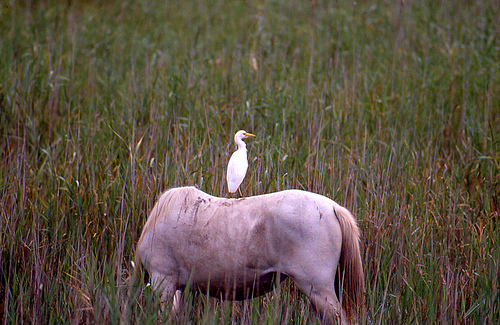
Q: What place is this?
A: It is a field.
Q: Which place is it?
A: It is a field.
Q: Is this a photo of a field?
A: Yes, it is showing a field.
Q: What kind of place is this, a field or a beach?
A: It is a field.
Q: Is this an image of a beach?
A: No, the picture is showing a field.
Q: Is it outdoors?
A: Yes, it is outdoors.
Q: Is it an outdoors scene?
A: Yes, it is outdoors.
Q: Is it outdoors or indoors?
A: It is outdoors.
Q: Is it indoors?
A: No, it is outdoors.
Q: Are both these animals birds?
A: No, they are horses and birds.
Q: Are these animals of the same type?
A: No, they are horses and birds.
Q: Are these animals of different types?
A: Yes, they are horses and birds.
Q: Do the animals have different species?
A: Yes, they are horses and birds.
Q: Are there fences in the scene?
A: No, there are no fences.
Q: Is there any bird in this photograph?
A: Yes, there is a bird.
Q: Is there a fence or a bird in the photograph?
A: Yes, there is a bird.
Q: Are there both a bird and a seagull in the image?
A: No, there is a bird but no seagulls.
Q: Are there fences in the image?
A: No, there are no fences.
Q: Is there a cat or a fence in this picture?
A: No, there are no fences or cats.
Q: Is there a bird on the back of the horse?
A: Yes, there is a bird on the back of the horse.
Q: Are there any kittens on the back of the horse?
A: No, there is a bird on the back of the horse.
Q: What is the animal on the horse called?
A: The animal is a bird.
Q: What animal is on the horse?
A: The animal is a bird.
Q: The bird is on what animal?
A: The bird is on the horse.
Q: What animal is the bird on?
A: The bird is on the horse.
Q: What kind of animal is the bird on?
A: The bird is on the horse.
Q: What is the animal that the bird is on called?
A: The animal is a horse.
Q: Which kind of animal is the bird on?
A: The bird is on the horse.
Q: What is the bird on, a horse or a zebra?
A: The bird is on a horse.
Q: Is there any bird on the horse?
A: Yes, there is a bird on the horse.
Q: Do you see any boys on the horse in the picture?
A: No, there is a bird on the horse.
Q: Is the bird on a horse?
A: Yes, the bird is on a horse.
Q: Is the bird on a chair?
A: No, the bird is on a horse.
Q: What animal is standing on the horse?
A: The bird is standing on the horse.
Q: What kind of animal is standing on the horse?
A: The animal is a bird.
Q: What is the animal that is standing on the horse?
A: The animal is a bird.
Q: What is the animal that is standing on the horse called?
A: The animal is a bird.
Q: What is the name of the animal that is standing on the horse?
A: The animal is a bird.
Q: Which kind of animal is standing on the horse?
A: The animal is a bird.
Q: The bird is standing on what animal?
A: The bird is standing on the horse.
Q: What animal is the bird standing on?
A: The bird is standing on the horse.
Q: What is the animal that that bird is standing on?
A: The animal is a horse.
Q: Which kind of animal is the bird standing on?
A: The bird is standing on the horse.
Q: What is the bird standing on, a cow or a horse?
A: The bird is standing on a horse.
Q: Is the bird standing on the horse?
A: Yes, the bird is standing on the horse.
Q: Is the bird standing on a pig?
A: No, the bird is standing on the horse.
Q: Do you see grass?
A: Yes, there is grass.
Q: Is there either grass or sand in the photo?
A: Yes, there is grass.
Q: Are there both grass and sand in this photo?
A: No, there is grass but no sand.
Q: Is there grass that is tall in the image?
A: Yes, there is tall grass.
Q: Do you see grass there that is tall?
A: Yes, there is grass that is tall.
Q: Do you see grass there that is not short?
A: Yes, there is tall grass.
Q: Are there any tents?
A: No, there are no tents.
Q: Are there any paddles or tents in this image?
A: No, there are no tents or paddles.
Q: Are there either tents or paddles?
A: No, there are no tents or paddles.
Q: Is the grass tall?
A: Yes, the grass is tall.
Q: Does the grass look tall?
A: Yes, the grass is tall.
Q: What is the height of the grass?
A: The grass is tall.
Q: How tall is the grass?
A: The grass is tall.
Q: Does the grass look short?
A: No, the grass is tall.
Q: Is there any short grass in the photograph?
A: No, there is grass but it is tall.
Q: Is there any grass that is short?
A: No, there is grass but it is tall.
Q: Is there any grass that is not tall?
A: No, there is grass but it is tall.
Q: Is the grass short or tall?
A: The grass is tall.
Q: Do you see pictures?
A: No, there are no pictures.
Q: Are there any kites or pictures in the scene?
A: No, there are no pictures or kites.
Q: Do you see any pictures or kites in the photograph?
A: No, there are no pictures or kites.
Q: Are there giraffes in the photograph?
A: No, there are no giraffes.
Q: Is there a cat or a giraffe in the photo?
A: No, there are no giraffes or cats.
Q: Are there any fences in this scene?
A: No, there are no fences.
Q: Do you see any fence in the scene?
A: No, there are no fences.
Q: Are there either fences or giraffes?
A: No, there are no fences or giraffes.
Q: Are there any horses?
A: Yes, there is a horse.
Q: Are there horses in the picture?
A: Yes, there is a horse.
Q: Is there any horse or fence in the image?
A: Yes, there is a horse.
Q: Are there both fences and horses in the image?
A: No, there is a horse but no fences.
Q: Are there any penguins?
A: No, there are no penguins.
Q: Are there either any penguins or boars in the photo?
A: No, there are no penguins or boars.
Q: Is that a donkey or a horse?
A: That is a horse.